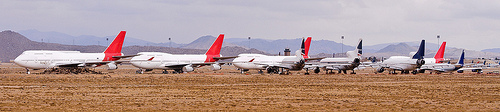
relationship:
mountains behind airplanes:
[0, 31, 498, 69] [16, 27, 470, 74]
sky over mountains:
[2, 0, 498, 52] [0, 31, 498, 69]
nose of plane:
[14, 49, 28, 67] [13, 27, 122, 74]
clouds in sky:
[311, 6, 409, 30] [3, 2, 484, 45]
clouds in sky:
[0, 6, 499, 30] [5, 4, 485, 50]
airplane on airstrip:
[10, 30, 142, 74] [4, 58, 481, 75]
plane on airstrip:
[126, 32, 239, 74] [3, 58, 478, 78]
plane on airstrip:
[228, 34, 321, 71] [3, 62, 482, 78]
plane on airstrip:
[304, 39, 367, 79] [3, 61, 484, 79]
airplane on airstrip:
[373, 39, 425, 75] [3, 56, 484, 88]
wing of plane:
[109, 49, 145, 63] [12, 29, 132, 74]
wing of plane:
[347, 38, 362, 63] [305, 38, 377, 73]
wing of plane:
[435, 40, 450, 60] [417, 39, 458, 73]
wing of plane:
[454, 49, 469, 69] [423, 50, 469, 77]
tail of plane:
[101, 29, 132, 51] [10, 28, 137, 78]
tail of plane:
[203, 30, 230, 56] [126, 32, 239, 71]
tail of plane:
[298, 32, 316, 56] [230, 33, 320, 74]